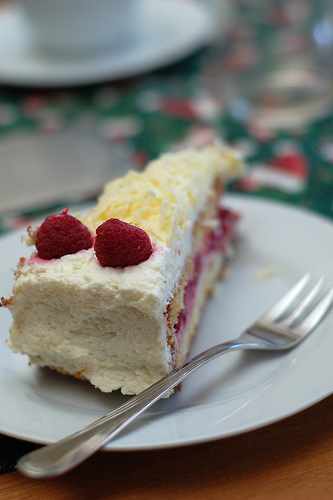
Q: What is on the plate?
A: Slice of cake.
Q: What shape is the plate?
A: Round.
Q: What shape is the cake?
A: Triangle.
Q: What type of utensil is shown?
A: Fork.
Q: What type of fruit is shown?
A: Raspberries.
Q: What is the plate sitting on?
A: Table.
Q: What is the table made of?
A: Wood.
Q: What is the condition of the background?
A: Blurry.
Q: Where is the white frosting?
A: On the cake.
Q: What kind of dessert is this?
A: Cake.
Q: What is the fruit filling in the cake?
A: Raspberry.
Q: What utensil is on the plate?
A: Fork.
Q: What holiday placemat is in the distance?
A: Christmas.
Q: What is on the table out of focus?
A: Glass.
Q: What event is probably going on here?
A: Christmas party.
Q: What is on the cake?
A: Frosting.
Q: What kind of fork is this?
A: Dessert fork.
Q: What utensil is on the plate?
A: Fork.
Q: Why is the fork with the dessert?
A: To use to eat.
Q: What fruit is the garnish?
A: Raspberry.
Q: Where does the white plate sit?
A: Wood table.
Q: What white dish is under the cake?
A: Plate.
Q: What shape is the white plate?
A: Round.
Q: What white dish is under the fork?
A: Plate.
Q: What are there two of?
A: Raspberries.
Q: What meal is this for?
A: Dessert.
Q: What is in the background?
A: Clear glass.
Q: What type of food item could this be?
A: Cheesecake.